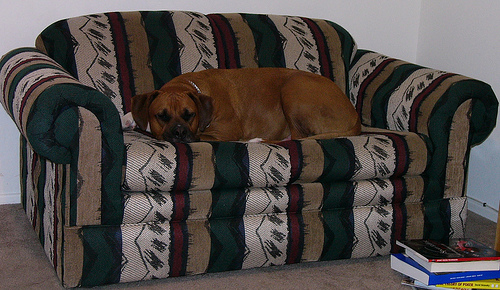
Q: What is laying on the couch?
A: Brown dog.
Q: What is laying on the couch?
A: Brown dog.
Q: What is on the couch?
A: Brown dog.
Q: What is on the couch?
A: Brown dog.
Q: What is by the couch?
A: Books.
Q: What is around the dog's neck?
A: A collar.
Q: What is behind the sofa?
A: A white wall.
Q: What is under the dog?
A: The sofa.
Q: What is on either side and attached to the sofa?
A: Armrests.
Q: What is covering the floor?
A: A tan carpet.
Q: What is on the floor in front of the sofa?
A: A stack of books.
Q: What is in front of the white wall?
A: The sofa.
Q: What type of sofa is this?
A: A love seat.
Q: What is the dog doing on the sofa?
A: Sleeping.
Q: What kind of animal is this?
A: Dog.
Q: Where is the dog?
A: Couch.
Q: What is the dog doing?
A: Lying on couch.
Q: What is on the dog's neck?
A: Collar.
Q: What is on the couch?
A: Striped pattern.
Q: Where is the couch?
A: Corner of room.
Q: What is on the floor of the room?
A: Rug.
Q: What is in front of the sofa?
A: Stack of books.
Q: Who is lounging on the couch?
A: A dog.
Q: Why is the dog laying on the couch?
A: To rest.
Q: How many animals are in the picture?
A: One.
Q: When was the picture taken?
A: Daytime.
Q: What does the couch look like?
A: Striped.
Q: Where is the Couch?
A: Against the wall.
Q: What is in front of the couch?
A: Books.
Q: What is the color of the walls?
A: White.